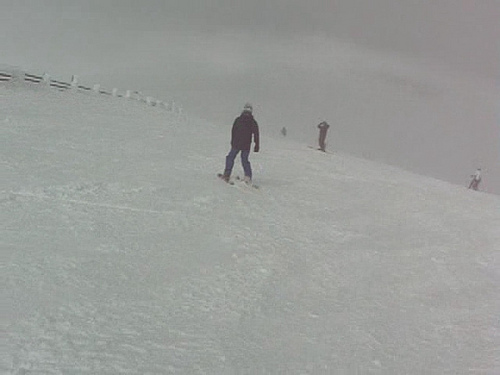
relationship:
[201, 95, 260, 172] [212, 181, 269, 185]
person on skis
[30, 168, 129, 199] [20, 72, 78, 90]
snow on fence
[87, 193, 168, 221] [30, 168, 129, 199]
tracks in snow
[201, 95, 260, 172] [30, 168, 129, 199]
person in snow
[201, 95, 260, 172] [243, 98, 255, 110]
person wearing cap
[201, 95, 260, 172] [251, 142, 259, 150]
person wearing gloves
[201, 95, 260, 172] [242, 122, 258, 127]
person wearing scarf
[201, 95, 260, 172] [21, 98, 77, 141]
person on slope